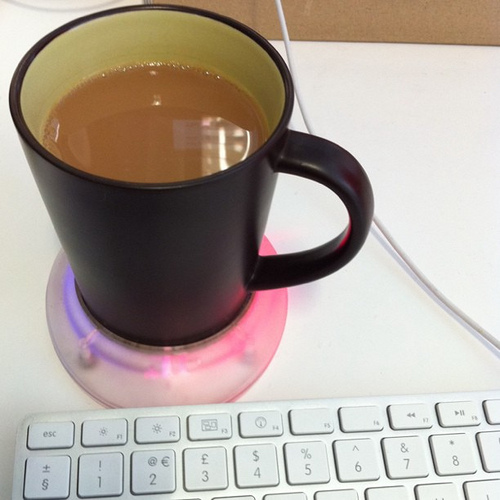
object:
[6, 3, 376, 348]
cup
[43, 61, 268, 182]
coffee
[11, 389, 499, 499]
keyboard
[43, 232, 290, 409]
cuprest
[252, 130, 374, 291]
handle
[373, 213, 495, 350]
cord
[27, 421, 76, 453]
escape key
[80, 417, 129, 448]
f1 key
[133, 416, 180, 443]
f2 key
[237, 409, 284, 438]
f4 key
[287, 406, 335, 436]
f5 key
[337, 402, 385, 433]
f6 key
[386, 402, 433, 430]
f7 key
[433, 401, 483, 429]
f8 key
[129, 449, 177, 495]
#2 key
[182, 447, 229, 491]
#3 key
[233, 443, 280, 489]
#4 key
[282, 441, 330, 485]
#5 key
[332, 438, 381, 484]
#6 key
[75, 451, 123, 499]
#1 key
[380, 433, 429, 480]
#7 key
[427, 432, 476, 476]
#8 key